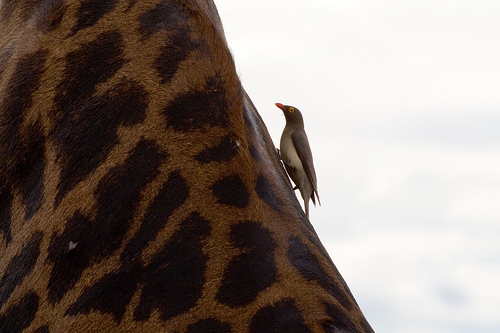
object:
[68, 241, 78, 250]
white blotch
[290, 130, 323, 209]
feathers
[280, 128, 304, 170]
grey underbelly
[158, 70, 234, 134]
black spot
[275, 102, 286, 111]
beak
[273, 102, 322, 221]
bird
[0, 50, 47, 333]
spots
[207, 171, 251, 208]
spot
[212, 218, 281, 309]
spot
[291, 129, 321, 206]
wing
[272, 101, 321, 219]
parasite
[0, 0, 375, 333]
neck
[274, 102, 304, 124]
head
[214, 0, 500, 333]
sky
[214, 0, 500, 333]
clouds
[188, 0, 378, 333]
spine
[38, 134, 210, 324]
black spot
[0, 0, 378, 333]
hide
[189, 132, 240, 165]
black spot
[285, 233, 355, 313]
spot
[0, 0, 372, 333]
animal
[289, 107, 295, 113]
eye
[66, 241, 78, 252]
fly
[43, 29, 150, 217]
spot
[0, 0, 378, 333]
fur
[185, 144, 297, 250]
area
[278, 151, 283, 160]
leg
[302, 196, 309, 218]
tail